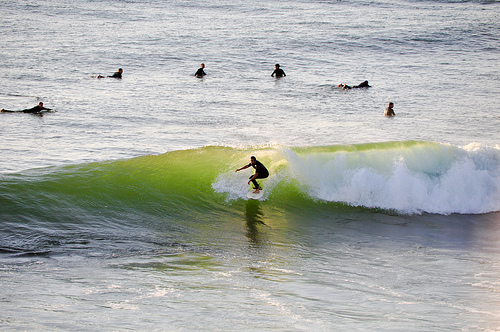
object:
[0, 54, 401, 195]
seven people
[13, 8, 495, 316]
ocean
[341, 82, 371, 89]
wetsuit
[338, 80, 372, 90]
person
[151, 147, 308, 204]
reflection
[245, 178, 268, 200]
surfboard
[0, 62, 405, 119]
group.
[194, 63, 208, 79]
surfers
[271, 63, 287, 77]
surfers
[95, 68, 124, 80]
surfer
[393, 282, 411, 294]
ocean ripple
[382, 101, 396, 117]
man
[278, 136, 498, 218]
white foam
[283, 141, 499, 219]
caps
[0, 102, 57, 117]
person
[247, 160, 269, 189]
suit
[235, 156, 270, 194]
guy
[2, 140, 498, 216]
wave